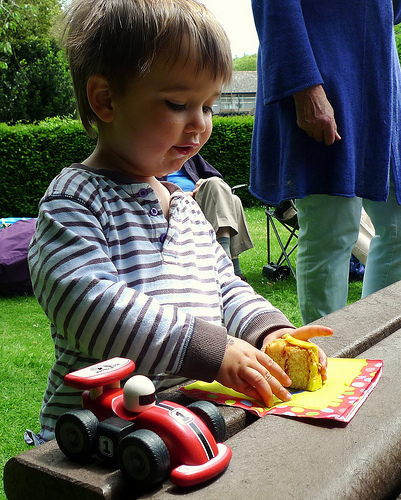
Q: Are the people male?
A: No, they are both male and female.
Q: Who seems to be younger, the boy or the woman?
A: The boy is younger than the woman.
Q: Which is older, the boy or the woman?
A: The woman is older than the boy.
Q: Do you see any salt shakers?
A: No, there are no salt shakers.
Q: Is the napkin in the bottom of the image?
A: Yes, the napkin is in the bottom of the image.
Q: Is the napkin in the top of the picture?
A: No, the napkin is in the bottom of the image.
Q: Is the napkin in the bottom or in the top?
A: The napkin is in the bottom of the image.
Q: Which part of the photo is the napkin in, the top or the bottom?
A: The napkin is in the bottom of the image.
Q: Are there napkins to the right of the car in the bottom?
A: Yes, there is a napkin to the right of the car.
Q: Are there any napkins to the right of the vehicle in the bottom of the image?
A: Yes, there is a napkin to the right of the car.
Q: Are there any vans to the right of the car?
A: No, there is a napkin to the right of the car.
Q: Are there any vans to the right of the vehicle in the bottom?
A: No, there is a napkin to the right of the car.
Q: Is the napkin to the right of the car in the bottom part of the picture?
A: Yes, the napkin is to the right of the car.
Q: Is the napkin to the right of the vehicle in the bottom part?
A: Yes, the napkin is to the right of the car.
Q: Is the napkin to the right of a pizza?
A: No, the napkin is to the right of the car.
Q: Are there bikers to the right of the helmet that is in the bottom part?
A: No, there is a napkin to the right of the helmet.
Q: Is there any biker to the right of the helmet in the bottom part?
A: No, there is a napkin to the right of the helmet.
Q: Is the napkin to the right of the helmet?
A: Yes, the napkin is to the right of the helmet.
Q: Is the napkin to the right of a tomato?
A: No, the napkin is to the right of the helmet.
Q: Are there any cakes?
A: Yes, there is a cake.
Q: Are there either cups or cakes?
A: Yes, there is a cake.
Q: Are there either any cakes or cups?
A: Yes, there is a cake.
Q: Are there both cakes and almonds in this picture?
A: No, there is a cake but no almonds.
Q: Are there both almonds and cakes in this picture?
A: No, there is a cake but no almonds.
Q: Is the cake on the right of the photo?
A: Yes, the cake is on the right of the image.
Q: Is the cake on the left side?
A: No, the cake is on the right of the image.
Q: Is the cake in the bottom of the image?
A: Yes, the cake is in the bottom of the image.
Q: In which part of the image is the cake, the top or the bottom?
A: The cake is in the bottom of the image.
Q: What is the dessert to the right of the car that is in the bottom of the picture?
A: The dessert is a cake.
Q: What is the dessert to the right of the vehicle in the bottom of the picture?
A: The dessert is a cake.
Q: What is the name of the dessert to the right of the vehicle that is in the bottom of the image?
A: The dessert is a cake.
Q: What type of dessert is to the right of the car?
A: The dessert is a cake.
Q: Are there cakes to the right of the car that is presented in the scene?
A: Yes, there is a cake to the right of the car.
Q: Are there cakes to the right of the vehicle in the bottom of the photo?
A: Yes, there is a cake to the right of the car.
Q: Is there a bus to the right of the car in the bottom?
A: No, there is a cake to the right of the car.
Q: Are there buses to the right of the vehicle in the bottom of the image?
A: No, there is a cake to the right of the car.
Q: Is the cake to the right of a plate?
A: No, the cake is to the right of the car.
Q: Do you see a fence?
A: No, there are no fences.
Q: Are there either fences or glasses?
A: No, there are no fences or glasses.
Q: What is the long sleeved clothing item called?
A: The clothing item is a shirt.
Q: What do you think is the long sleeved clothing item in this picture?
A: The clothing item is a shirt.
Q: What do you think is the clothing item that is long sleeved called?
A: The clothing item is a shirt.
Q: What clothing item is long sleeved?
A: The clothing item is a shirt.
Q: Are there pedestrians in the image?
A: No, there are no pedestrians.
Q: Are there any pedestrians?
A: No, there are no pedestrians.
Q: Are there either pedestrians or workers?
A: No, there are no pedestrians or workers.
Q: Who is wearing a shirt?
A: The boy is wearing a shirt.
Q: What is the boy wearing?
A: The boy is wearing a shirt.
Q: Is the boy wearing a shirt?
A: Yes, the boy is wearing a shirt.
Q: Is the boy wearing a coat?
A: No, the boy is wearing a shirt.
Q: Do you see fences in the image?
A: No, there are no fences.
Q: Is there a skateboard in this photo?
A: No, there are no skateboards.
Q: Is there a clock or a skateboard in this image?
A: No, there are no skateboards or clocks.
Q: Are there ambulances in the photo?
A: No, there are no ambulances.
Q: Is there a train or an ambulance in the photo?
A: No, there are no ambulances or trains.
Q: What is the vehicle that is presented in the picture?
A: The vehicle is a car.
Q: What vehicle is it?
A: The vehicle is a car.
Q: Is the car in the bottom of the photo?
A: Yes, the car is in the bottom of the image.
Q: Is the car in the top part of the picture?
A: No, the car is in the bottom of the image.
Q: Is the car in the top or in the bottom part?
A: The car is in the bottom of the image.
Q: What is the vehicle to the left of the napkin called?
A: The vehicle is a car.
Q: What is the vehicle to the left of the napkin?
A: The vehicle is a car.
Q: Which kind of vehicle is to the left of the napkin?
A: The vehicle is a car.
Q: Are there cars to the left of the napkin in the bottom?
A: Yes, there is a car to the left of the napkin.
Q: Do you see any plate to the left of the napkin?
A: No, there is a car to the left of the napkin.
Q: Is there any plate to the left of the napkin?
A: No, there is a car to the left of the napkin.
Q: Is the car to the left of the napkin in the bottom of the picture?
A: Yes, the car is to the left of the napkin.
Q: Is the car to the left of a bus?
A: No, the car is to the left of the napkin.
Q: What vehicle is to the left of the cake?
A: The vehicle is a car.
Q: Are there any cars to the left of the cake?
A: Yes, there is a car to the left of the cake.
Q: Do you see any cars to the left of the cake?
A: Yes, there is a car to the left of the cake.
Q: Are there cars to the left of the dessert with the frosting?
A: Yes, there is a car to the left of the cake.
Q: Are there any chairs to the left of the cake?
A: No, there is a car to the left of the cake.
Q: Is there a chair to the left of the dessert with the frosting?
A: No, there is a car to the left of the cake.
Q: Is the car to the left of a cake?
A: Yes, the car is to the left of a cake.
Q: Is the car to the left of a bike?
A: No, the car is to the left of a cake.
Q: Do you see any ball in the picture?
A: No, there are no balls.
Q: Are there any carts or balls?
A: No, there are no balls or carts.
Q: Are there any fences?
A: No, there are no fences.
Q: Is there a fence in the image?
A: No, there are no fences.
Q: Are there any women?
A: Yes, there is a woman.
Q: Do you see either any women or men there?
A: Yes, there is a woman.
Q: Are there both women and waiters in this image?
A: No, there is a woman but no waiters.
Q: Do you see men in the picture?
A: No, there are no men.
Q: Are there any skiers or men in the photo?
A: No, there are no men or skiers.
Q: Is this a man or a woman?
A: This is a woman.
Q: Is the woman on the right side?
A: Yes, the woman is on the right of the image.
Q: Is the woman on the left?
A: No, the woman is on the right of the image.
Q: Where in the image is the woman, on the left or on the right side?
A: The woman is on the right of the image.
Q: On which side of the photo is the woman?
A: The woman is on the right of the image.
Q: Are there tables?
A: Yes, there is a table.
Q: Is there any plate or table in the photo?
A: Yes, there is a table.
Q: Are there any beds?
A: No, there are no beds.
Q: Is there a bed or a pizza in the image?
A: No, there are no beds or pizzas.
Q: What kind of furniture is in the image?
A: The furniture is a table.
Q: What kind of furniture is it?
A: The piece of furniture is a table.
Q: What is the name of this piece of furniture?
A: This is a table.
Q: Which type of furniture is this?
A: This is a table.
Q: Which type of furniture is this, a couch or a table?
A: This is a table.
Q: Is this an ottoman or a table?
A: This is a table.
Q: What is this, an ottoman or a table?
A: This is a table.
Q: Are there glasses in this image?
A: No, there are no glasses.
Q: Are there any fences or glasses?
A: No, there are no glasses or fences.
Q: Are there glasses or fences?
A: No, there are no glasses or fences.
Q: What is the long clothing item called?
A: The clothing item is a shirt.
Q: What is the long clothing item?
A: The clothing item is a shirt.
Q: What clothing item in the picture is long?
A: The clothing item is a shirt.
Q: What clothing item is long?
A: The clothing item is a shirt.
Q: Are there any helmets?
A: Yes, there is a helmet.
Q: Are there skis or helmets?
A: Yes, there is a helmet.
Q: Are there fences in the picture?
A: No, there are no fences.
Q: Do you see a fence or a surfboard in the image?
A: No, there are no fences or surfboards.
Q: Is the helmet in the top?
A: No, the helmet is in the bottom of the image.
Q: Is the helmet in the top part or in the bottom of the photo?
A: The helmet is in the bottom of the image.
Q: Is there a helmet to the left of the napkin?
A: Yes, there is a helmet to the left of the napkin.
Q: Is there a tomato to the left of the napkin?
A: No, there is a helmet to the left of the napkin.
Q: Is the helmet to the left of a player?
A: No, the helmet is to the left of the napkin.